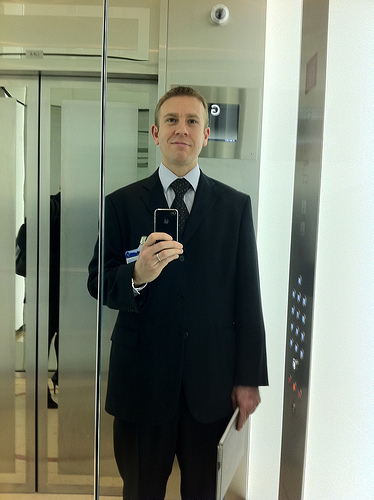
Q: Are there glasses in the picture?
A: No, there are no glasses.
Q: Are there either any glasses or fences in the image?
A: No, there are no glasses or fences.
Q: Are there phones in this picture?
A: Yes, there is a phone.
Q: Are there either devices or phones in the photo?
A: Yes, there is a phone.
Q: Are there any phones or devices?
A: Yes, there is a phone.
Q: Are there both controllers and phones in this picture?
A: No, there is a phone but no controllers.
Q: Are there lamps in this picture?
A: No, there are no lamps.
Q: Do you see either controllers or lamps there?
A: No, there are no lamps or controllers.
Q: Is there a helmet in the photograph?
A: No, there are no helmets.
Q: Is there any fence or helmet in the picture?
A: No, there are no helmets or fences.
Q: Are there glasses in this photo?
A: No, there are no glasses.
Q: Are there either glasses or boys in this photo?
A: No, there are no glasses or boys.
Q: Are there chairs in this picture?
A: No, there are no chairs.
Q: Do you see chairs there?
A: No, there are no chairs.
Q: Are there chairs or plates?
A: No, there are no chairs or plates.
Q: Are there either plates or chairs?
A: No, there are no chairs or plates.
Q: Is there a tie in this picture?
A: Yes, there is a tie.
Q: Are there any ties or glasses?
A: Yes, there is a tie.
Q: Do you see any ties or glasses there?
A: Yes, there is a tie.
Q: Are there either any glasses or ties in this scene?
A: Yes, there is a tie.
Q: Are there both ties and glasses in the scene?
A: No, there is a tie but no glasses.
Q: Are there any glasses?
A: No, there are no glasses.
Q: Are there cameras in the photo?
A: Yes, there is a camera.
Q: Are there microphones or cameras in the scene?
A: Yes, there is a camera.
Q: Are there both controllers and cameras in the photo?
A: No, there is a camera but no controllers.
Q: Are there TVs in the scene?
A: No, there are no tvs.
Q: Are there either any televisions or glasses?
A: No, there are no televisions or glasses.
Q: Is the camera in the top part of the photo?
A: Yes, the camera is in the top of the image.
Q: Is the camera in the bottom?
A: No, the camera is in the top of the image.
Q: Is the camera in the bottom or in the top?
A: The camera is in the top of the image.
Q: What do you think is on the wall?
A: The camera is on the wall.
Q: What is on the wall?
A: The camera is on the wall.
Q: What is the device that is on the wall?
A: The device is a camera.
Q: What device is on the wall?
A: The device is a camera.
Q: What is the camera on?
A: The camera is on the wall.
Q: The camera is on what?
A: The camera is on the wall.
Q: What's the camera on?
A: The camera is on the wall.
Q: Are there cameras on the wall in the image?
A: Yes, there is a camera on the wall.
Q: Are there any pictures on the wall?
A: No, there is a camera on the wall.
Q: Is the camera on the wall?
A: Yes, the camera is on the wall.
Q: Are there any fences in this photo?
A: No, there are no fences.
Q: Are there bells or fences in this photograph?
A: No, there are no fences or bells.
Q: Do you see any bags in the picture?
A: No, there are no bags.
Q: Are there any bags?
A: No, there are no bags.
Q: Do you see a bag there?
A: No, there are no bags.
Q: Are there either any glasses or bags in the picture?
A: No, there are no bags or glasses.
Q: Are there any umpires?
A: No, there are no umpires.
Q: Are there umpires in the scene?
A: No, there are no umpires.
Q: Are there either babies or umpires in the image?
A: No, there are no umpires or babies.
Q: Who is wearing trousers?
A: The man is wearing trousers.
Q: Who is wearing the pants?
A: The man is wearing trousers.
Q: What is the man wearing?
A: The man is wearing trousers.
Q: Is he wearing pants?
A: Yes, the man is wearing pants.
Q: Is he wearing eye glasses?
A: No, the man is wearing pants.